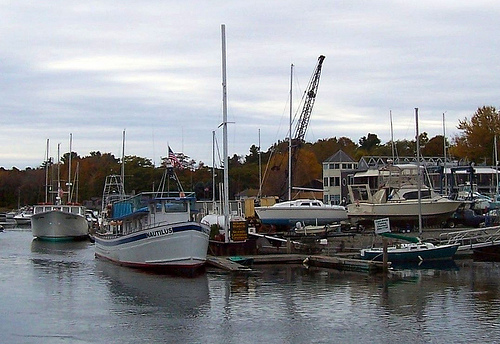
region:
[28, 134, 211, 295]
Two boats docked in water.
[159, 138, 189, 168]
American flag waving to top of boat.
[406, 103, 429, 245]
Tall mast on gree sailboat.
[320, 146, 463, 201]
Beige building beyond boat dock.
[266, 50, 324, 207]
Crane in background next to beige building.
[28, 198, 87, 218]
Windows across boat's pilot house.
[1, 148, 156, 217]
Trees growing in background beyond river.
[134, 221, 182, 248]
Boat's name written in blue on bow of boat.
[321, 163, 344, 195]
Windows on outside of beige building.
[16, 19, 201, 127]
Gray cloudy sky over river.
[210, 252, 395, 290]
Boat dock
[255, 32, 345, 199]
Long arm of a crane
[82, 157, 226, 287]
White and blue boat called "Nautilus"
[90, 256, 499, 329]
Rippled reflections of boats in the water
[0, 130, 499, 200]
Autumn trees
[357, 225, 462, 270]
Small green and white speed boat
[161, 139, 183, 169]
American flag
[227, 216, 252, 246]
Wooden barrel on the dock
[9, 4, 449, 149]
Overcast skies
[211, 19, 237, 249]
Tall white pole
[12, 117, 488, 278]
Boats at the dock.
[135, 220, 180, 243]
Boat is named "Nautilus".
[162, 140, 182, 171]
American flag flying on a boat.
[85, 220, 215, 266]
Boat is white with blue stripe.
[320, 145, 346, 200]
Building with glass windows.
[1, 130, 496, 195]
Trees with orange and green leaves.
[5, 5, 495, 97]
Gray and cloudy sky.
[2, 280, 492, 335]
The water is calm.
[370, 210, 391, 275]
Dock sign is white.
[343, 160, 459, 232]
Boat on wheels at the dock.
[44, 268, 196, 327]
the water is calm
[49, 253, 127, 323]
the water is rippled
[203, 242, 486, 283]
boats at the marina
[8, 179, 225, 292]
boats in the water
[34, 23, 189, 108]
the sky is cloudy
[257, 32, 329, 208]
the tall crane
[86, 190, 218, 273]
the boat is white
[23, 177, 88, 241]
the boat is white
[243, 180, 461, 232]
the boats on the marina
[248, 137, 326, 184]
the trees with brown leaves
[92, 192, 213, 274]
boat parked on dock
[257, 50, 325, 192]
large crane in the background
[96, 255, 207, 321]
reflection of boat on the water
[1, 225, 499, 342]
body of water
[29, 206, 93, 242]
front side of boat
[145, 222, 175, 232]
name marked on boat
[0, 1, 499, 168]
overcast sky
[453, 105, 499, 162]
tree with orange colored leaves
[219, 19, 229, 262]
sail pole of boat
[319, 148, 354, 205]
octagon shape building with windows